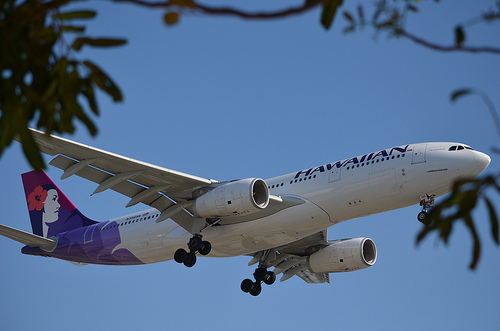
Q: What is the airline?
A: Hawaiian.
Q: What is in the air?
A: Plane.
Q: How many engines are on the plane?
A: 2.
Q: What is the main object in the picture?
A: A plane.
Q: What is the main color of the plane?
A: White.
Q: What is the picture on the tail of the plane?
A: A woman.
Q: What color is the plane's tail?
A: Purple.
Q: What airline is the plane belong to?
A: Hawaiian airline.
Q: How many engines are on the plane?
A: Two.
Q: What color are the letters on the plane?
A: Purple.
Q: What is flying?
A: The airplane.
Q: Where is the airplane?
A: In the sky.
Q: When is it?
A: Daytime.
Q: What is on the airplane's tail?
A: A woman's profile.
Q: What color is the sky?
A: Blue.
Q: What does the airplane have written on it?
A: Hawaiian.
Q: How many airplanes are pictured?
A: One.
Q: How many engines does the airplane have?
A: Two.